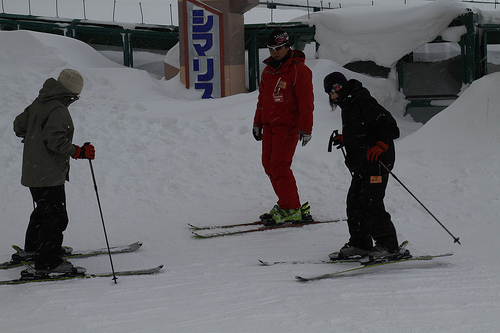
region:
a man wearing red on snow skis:
[177, 20, 330, 240]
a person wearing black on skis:
[274, 67, 458, 287]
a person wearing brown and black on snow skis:
[0, 65, 165, 292]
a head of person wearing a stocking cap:
[39, 63, 93, 107]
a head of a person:
[264, 22, 293, 62]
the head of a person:
[320, 65, 355, 112]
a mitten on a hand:
[69, 139, 101, 161]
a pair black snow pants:
[343, 170, 400, 247]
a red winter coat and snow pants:
[258, 59, 316, 206]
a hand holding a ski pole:
[79, 140, 122, 290]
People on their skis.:
[240, 61, 475, 289]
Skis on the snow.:
[255, 241, 474, 323]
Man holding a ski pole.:
[295, 75, 474, 287]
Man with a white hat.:
[40, 34, 104, 119]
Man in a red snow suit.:
[207, 32, 363, 220]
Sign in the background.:
[164, 7, 259, 132]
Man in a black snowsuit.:
[287, 61, 449, 261]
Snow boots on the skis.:
[235, 190, 310, 252]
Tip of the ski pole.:
[432, 207, 481, 280]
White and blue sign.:
[165, 15, 232, 120]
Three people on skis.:
[3, 25, 475, 292]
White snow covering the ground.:
[1, 8, 491, 331]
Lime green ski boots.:
[267, 194, 309, 224]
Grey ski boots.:
[335, 240, 407, 260]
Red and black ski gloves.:
[331, 132, 389, 162]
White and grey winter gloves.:
[246, 122, 311, 144]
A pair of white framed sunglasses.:
[263, 40, 287, 55]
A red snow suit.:
[254, 54, 319, 212]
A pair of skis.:
[189, 208, 355, 253]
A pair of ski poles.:
[326, 125, 467, 250]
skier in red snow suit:
[249, 27, 318, 227]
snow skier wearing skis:
[186, 28, 346, 238]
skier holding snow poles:
[323, 70, 465, 264]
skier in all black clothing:
[321, 70, 406, 267]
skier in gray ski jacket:
[13, 65, 98, 280]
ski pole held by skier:
[81, 142, 126, 285]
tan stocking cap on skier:
[56, 65, 86, 95]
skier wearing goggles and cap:
[248, 25, 315, 229]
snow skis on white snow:
[258, 237, 456, 287]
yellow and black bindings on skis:
[261, 203, 313, 228]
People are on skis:
[0, 26, 459, 291]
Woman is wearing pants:
[342, 165, 407, 250]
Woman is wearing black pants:
[341, 163, 403, 250]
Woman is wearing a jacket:
[334, 76, 401, 176]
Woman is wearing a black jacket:
[333, 76, 400, 174]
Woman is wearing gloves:
[331, 130, 391, 163]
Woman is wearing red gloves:
[332, 128, 393, 160]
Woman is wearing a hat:
[322, 67, 354, 94]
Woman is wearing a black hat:
[320, 66, 353, 94]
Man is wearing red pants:
[256, 120, 306, 207]